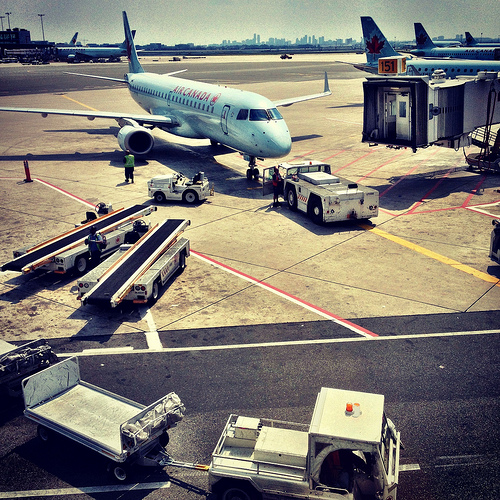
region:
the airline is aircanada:
[119, 58, 289, 160]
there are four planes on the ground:
[339, 14, 498, 80]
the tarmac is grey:
[264, 339, 459, 376]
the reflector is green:
[106, 153, 158, 181]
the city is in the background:
[210, 20, 350, 50]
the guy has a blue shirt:
[74, 231, 116, 264]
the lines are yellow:
[398, 241, 464, 276]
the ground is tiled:
[240, 232, 378, 294]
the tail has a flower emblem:
[362, 32, 392, 51]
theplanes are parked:
[352, 19, 498, 86]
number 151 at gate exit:
[366, 49, 422, 87]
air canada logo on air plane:
[155, 82, 219, 113]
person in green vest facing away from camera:
[110, 138, 155, 191]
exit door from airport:
[373, 79, 433, 162]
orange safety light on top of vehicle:
[338, 395, 354, 421]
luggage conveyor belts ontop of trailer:
[75, 208, 168, 320]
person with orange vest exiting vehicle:
[260, 157, 286, 222]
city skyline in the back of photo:
[232, 27, 365, 58]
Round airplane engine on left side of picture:
[117, 111, 168, 171]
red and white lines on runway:
[218, 278, 335, 328]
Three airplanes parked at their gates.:
[341, 12, 498, 81]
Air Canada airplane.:
[0, 7, 330, 187]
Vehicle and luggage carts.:
[0, 331, 406, 499]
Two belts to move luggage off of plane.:
[0, 203, 195, 311]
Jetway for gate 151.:
[355, 53, 498, 155]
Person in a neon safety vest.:
[122, 146, 134, 182]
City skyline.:
[208, 31, 363, 53]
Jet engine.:
[118, 123, 153, 156]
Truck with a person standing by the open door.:
[259, 156, 380, 226]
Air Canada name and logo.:
[171, 82, 221, 109]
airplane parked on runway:
[40, 5, 288, 161]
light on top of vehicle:
[332, 397, 365, 424]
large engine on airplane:
[108, 119, 161, 162]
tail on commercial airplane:
[353, 13, 394, 63]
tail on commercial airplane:
[113, 10, 146, 73]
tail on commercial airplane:
[409, 15, 432, 51]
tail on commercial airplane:
[458, 26, 479, 47]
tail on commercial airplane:
[63, 25, 81, 45]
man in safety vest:
[110, 142, 136, 182]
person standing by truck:
[262, 156, 289, 202]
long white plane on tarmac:
[2, 11, 334, 181]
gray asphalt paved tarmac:
[0, 55, 495, 495]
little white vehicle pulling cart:
[200, 385, 400, 495]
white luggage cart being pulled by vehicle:
[16, 355, 181, 471]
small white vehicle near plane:
[147, 170, 208, 205]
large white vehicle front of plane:
[252, 157, 377, 222]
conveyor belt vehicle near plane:
[77, 215, 187, 310]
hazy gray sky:
[1, 2, 493, 42]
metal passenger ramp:
[357, 65, 494, 145]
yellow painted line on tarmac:
[361, 217, 496, 287]